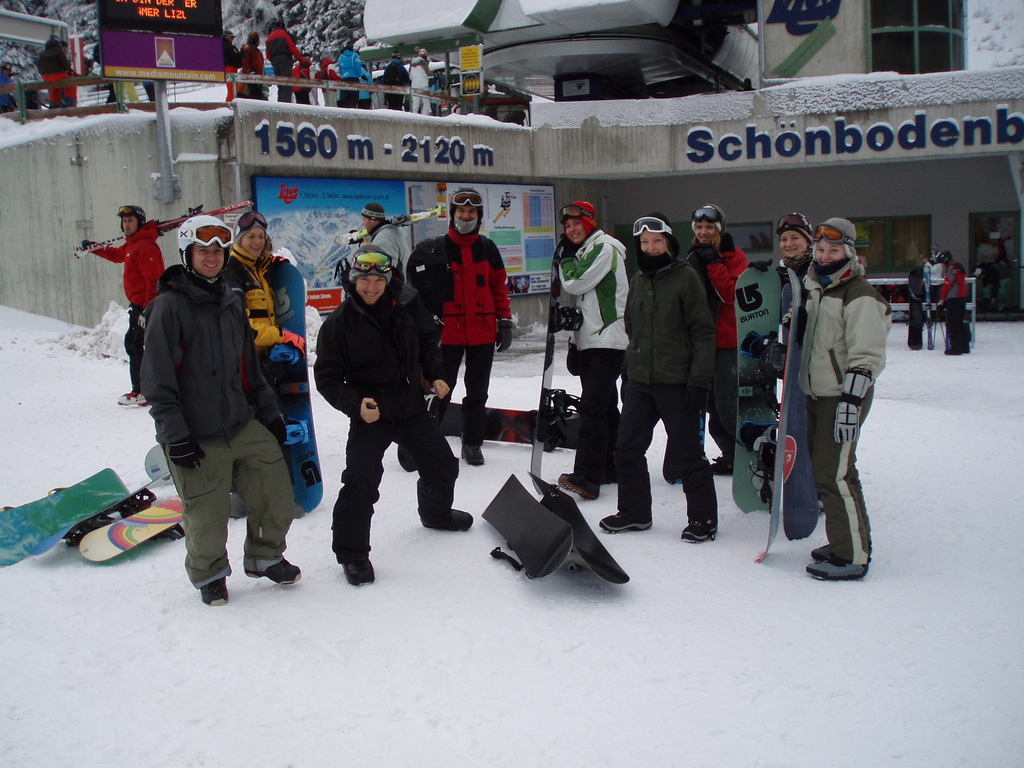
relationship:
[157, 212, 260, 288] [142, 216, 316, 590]
helmet on man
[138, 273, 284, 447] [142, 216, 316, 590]
jacket on man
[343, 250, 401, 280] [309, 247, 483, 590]
ski goggles on man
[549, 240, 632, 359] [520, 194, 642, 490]
jacket on skier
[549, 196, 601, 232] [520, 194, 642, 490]
cap on skier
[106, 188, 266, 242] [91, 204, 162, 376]
skis on man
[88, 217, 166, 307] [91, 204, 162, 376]
jacket on man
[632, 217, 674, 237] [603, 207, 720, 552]
goggles on girl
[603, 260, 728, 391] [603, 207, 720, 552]
jacket on girl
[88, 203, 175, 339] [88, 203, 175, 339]
jacket on skier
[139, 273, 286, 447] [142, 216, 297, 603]
jacket on man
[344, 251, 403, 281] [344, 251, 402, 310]
ski goggles on person's head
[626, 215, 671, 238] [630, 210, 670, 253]
goggles on head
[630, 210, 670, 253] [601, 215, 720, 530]
head on person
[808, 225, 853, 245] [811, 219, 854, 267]
goggles on head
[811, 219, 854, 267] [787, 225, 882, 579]
head on person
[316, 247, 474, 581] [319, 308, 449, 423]
man wearing jacket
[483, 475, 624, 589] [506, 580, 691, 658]
snowboards on snow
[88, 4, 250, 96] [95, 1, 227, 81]
digital display on wall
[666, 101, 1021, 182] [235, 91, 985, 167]
resort name on wall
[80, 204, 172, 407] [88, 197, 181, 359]
man wearing jacket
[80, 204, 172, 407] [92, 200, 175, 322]
man wearing jacket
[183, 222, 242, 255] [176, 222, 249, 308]
ski goggles on head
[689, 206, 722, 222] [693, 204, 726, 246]
goggles on head